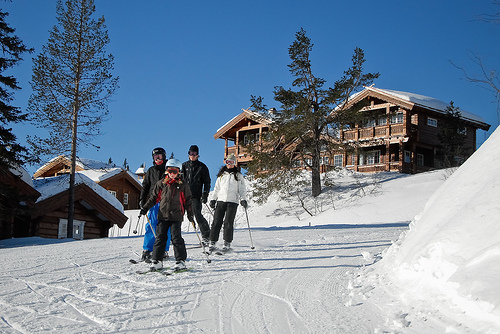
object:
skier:
[207, 154, 249, 252]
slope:
[11, 214, 371, 316]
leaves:
[292, 44, 307, 54]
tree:
[244, 29, 383, 213]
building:
[217, 85, 489, 176]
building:
[29, 171, 126, 240]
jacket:
[211, 171, 248, 204]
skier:
[138, 148, 172, 259]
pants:
[143, 202, 171, 252]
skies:
[216, 244, 233, 256]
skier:
[139, 159, 199, 274]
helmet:
[165, 158, 183, 170]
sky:
[0, 1, 500, 187]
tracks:
[252, 291, 309, 319]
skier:
[180, 144, 213, 246]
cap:
[189, 144, 198, 152]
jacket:
[139, 160, 169, 207]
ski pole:
[239, 199, 260, 250]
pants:
[209, 200, 239, 243]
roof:
[327, 84, 491, 122]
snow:
[413, 94, 432, 103]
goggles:
[168, 168, 179, 174]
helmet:
[151, 147, 166, 156]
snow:
[313, 182, 428, 286]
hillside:
[378, 129, 500, 321]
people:
[136, 144, 247, 277]